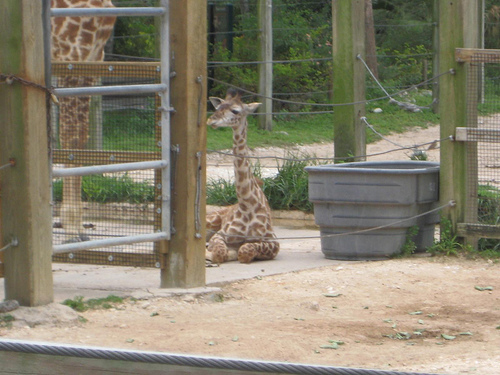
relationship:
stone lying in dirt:
[321, 289, 344, 303] [0, 244, 497, 374]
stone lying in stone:
[471, 282, 496, 297] [321, 289, 344, 303]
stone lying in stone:
[316, 339, 343, 352] [321, 289, 344, 303]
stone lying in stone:
[148, 308, 163, 322] [321, 289, 344, 303]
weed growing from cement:
[63, 290, 87, 314] [2, 211, 356, 304]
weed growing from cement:
[60, 291, 136, 312] [2, 211, 356, 304]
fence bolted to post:
[2, 3, 489, 305] [154, 0, 213, 287]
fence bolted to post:
[2, 3, 489, 305] [2, 0, 65, 303]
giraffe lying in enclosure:
[206, 86, 281, 269] [2, 2, 484, 372]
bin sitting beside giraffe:
[303, 159, 440, 261] [204, 83, 286, 265]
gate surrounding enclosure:
[43, 5, 173, 255] [2, 2, 484, 372]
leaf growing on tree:
[279, 61, 283, 65] [210, 1, 320, 116]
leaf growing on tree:
[243, 68, 249, 74] [210, 1, 320, 116]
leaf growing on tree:
[240, 41, 246, 43] [210, 1, 320, 116]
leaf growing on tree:
[244, 20, 247, 22] [210, 1, 320, 116]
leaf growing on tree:
[276, 63, 279, 68] [210, 1, 320, 116]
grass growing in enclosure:
[49, 147, 485, 248] [2, 2, 484, 372]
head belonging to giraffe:
[202, 94, 248, 129] [204, 83, 286, 265]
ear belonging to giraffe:
[241, 100, 263, 116] [136, 100, 364, 331]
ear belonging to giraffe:
[206, 94, 223, 108] [136, 100, 364, 331]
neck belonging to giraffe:
[229, 127, 265, 198] [204, 83, 286, 265]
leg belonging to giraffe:
[204, 227, 230, 265] [178, 114, 266, 262]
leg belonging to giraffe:
[234, 237, 279, 261] [178, 114, 266, 262]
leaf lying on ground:
[230, 334, 239, 342] [0, 112, 498, 365]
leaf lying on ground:
[206, 339, 215, 348] [0, 112, 498, 365]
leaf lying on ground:
[320, 340, 340, 350] [0, 112, 498, 365]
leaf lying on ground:
[437, 330, 458, 340] [0, 112, 498, 365]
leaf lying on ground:
[408, 308, 423, 317] [0, 112, 498, 365]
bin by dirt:
[303, 159, 440, 261] [0, 112, 500, 375]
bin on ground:
[303, 159, 440, 261] [0, 112, 498, 365]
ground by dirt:
[0, 112, 498, 365] [2, 111, 497, 369]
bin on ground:
[303, 159, 440, 261] [0, 213, 497, 374]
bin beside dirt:
[303, 159, 440, 261] [303, 245, 421, 340]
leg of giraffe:
[237, 237, 278, 263] [204, 83, 286, 265]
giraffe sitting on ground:
[187, 75, 297, 266] [163, 211, 329, 290]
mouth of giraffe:
[206, 118, 221, 132] [204, 83, 286, 265]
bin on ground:
[303, 159, 440, 261] [244, 264, 481, 335]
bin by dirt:
[303, 159, 440, 261] [0, 244, 497, 374]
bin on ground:
[303, 159, 440, 261] [278, 220, 319, 273]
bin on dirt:
[303, 159, 440, 261] [0, 244, 497, 374]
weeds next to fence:
[430, 203, 498, 265] [427, 55, 498, 247]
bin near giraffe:
[289, 151, 442, 251] [157, 77, 299, 293]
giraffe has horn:
[206, 86, 281, 269] [230, 91, 240, 101]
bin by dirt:
[303, 159, 440, 261] [200, 244, 481, 364]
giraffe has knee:
[206, 86, 281, 269] [236, 241, 260, 261]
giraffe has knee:
[206, 86, 281, 269] [208, 246, 230, 261]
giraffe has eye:
[206, 86, 281, 269] [230, 108, 239, 115]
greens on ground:
[311, 286, 497, 352] [3, 75, 498, 372]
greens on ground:
[410, 310, 424, 315] [3, 75, 498, 372]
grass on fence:
[47, 74, 500, 264] [102, 52, 332, 209]